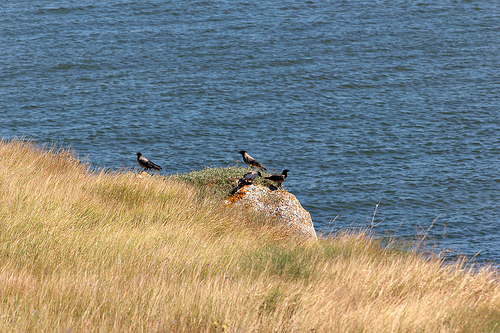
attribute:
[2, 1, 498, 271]
water — body, blue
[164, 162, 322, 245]
rock — orange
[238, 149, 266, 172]
bird — perched, black, sitting,  plenty,  visible, plenty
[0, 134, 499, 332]
grass — green, brown, tall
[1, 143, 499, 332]
field — grass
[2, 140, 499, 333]
meadow — green